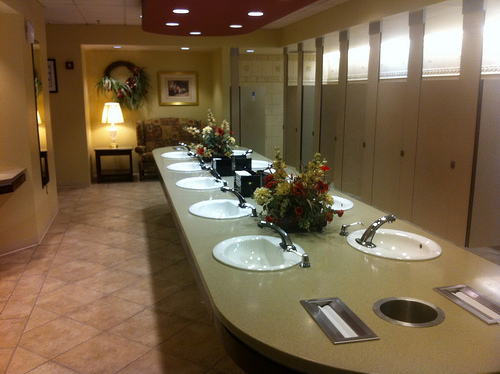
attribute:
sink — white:
[212, 219, 313, 279]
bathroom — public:
[9, 8, 499, 270]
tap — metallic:
[258, 217, 299, 250]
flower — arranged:
[258, 148, 338, 221]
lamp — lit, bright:
[89, 95, 131, 153]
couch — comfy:
[133, 113, 192, 145]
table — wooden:
[91, 145, 138, 179]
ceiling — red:
[50, 4, 334, 40]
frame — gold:
[156, 67, 201, 111]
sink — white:
[194, 197, 254, 227]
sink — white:
[182, 174, 226, 193]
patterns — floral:
[157, 124, 183, 139]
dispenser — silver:
[298, 290, 384, 351]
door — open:
[244, 89, 275, 140]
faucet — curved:
[362, 209, 397, 247]